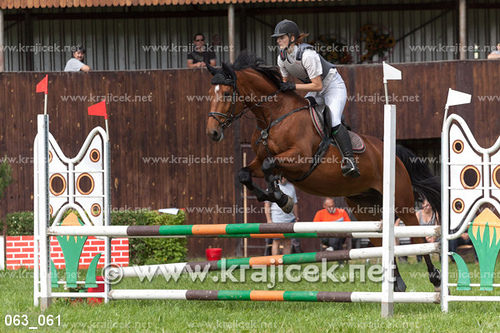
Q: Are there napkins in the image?
A: No, there are no napkins.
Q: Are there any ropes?
A: No, there are no ropes.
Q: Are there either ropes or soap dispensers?
A: No, there are no ropes or soap dispensers.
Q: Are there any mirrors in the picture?
A: No, there are no mirrors.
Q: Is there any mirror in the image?
A: No, there are no mirrors.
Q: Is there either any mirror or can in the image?
A: No, there are no mirrors or cans.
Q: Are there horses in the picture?
A: Yes, there is a horse.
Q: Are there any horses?
A: Yes, there is a horse.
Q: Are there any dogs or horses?
A: Yes, there is a horse.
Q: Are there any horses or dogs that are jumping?
A: Yes, the horse is jumping.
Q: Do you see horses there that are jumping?
A: Yes, there is a horse that is jumping.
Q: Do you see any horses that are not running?
A: Yes, there is a horse that is jumping .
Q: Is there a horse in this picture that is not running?
A: Yes, there is a horse that is jumping.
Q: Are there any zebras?
A: No, there are no zebras.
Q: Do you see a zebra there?
A: No, there are no zebras.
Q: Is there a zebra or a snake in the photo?
A: No, there are no zebras or snakes.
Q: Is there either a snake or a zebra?
A: No, there are no zebras or snakes.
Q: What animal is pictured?
A: The animal is a horse.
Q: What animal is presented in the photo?
A: The animal is a horse.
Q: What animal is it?
A: The animal is a horse.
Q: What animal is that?
A: This is a horse.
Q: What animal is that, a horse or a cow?
A: This is a horse.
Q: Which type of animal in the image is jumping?
A: The animal is a horse.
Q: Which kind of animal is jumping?
A: The animal is a horse.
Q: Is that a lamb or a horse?
A: That is a horse.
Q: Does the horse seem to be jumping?
A: Yes, the horse is jumping.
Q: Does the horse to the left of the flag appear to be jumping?
A: Yes, the horse is jumping.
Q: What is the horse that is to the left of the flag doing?
A: The horse is jumping.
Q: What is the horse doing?
A: The horse is jumping.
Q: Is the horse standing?
A: No, the horse is jumping.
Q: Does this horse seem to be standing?
A: No, the horse is jumping.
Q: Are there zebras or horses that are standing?
A: No, there is a horse but it is jumping.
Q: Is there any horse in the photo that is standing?
A: No, there is a horse but it is jumping.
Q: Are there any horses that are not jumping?
A: No, there is a horse but it is jumping.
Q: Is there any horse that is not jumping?
A: No, there is a horse but it is jumping.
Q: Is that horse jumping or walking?
A: The horse is jumping.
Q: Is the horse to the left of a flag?
A: Yes, the horse is to the left of a flag.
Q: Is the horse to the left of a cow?
A: No, the horse is to the left of a flag.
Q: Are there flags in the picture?
A: Yes, there is a flag.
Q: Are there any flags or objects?
A: Yes, there is a flag.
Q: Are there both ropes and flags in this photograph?
A: No, there is a flag but no ropes.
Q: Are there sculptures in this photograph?
A: No, there are no sculptures.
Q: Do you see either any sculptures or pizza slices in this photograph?
A: No, there are no sculptures or pizza slices.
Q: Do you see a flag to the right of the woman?
A: Yes, there is a flag to the right of the woman.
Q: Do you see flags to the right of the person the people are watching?
A: Yes, there is a flag to the right of the woman.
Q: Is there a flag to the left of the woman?
A: No, the flag is to the right of the woman.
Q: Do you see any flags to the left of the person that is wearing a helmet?
A: No, the flag is to the right of the woman.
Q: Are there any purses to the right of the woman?
A: No, there is a flag to the right of the woman.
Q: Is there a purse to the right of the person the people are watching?
A: No, there is a flag to the right of the woman.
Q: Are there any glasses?
A: No, there are no glasses.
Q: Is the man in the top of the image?
A: Yes, the man is in the top of the image.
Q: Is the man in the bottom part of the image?
A: No, the man is in the top of the image.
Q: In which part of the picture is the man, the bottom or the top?
A: The man is in the top of the image.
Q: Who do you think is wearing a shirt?
A: The man is wearing a shirt.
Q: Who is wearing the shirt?
A: The man is wearing a shirt.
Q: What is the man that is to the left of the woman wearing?
A: The man is wearing a shirt.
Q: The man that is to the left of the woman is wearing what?
A: The man is wearing a shirt.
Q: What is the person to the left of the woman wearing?
A: The man is wearing a shirt.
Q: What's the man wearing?
A: The man is wearing a shirt.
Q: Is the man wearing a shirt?
A: Yes, the man is wearing a shirt.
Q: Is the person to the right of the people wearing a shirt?
A: Yes, the man is wearing a shirt.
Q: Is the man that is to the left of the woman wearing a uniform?
A: No, the man is wearing a shirt.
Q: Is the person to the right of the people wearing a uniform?
A: No, the man is wearing a shirt.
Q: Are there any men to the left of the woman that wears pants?
A: Yes, there is a man to the left of the woman.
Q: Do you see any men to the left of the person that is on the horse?
A: Yes, there is a man to the left of the woman.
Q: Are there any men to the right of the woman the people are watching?
A: No, the man is to the left of the woman.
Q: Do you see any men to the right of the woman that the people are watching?
A: No, the man is to the left of the woman.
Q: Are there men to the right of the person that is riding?
A: No, the man is to the left of the woman.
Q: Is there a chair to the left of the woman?
A: No, there is a man to the left of the woman.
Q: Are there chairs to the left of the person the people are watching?
A: No, there is a man to the left of the woman.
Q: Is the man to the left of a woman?
A: Yes, the man is to the left of a woman.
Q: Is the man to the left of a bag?
A: No, the man is to the left of a woman.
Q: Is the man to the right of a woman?
A: No, the man is to the left of a woman.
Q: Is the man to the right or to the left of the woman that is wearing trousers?
A: The man is to the left of the woman.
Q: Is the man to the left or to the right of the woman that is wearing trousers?
A: The man is to the left of the woman.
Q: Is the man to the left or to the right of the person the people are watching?
A: The man is to the left of the woman.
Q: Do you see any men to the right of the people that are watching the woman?
A: Yes, there is a man to the right of the people.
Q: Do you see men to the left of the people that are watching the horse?
A: No, the man is to the right of the people.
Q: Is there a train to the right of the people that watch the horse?
A: No, there is a man to the right of the people.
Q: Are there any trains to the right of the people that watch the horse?
A: No, there is a man to the right of the people.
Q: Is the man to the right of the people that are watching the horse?
A: Yes, the man is to the right of the people.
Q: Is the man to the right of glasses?
A: No, the man is to the right of the people.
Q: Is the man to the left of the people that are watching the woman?
A: No, the man is to the right of the people.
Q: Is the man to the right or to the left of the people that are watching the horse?
A: The man is to the right of the people.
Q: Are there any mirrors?
A: No, there are no mirrors.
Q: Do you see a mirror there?
A: No, there are no mirrors.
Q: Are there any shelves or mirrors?
A: No, there are no mirrors or shelves.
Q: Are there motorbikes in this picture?
A: No, there are no motorbikes.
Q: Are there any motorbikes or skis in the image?
A: No, there are no motorbikes or skis.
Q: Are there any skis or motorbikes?
A: No, there are no motorbikes or skis.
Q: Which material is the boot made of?
A: The boot is made of leather.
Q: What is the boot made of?
A: The boot is made of leather.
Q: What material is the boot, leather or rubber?
A: The boot is made of leather.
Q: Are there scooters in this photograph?
A: No, there are no scooters.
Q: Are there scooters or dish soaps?
A: No, there are no scooters or dish soaps.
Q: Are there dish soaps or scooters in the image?
A: No, there are no scooters or dish soaps.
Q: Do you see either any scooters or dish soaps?
A: No, there are no scooters or dish soaps.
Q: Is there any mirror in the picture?
A: No, there are no mirrors.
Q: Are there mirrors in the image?
A: No, there are no mirrors.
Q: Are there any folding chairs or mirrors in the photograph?
A: No, there are no mirrors or folding chairs.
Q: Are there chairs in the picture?
A: No, there are no chairs.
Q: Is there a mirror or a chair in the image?
A: No, there are no chairs or mirrors.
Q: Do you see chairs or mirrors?
A: No, there are no chairs or mirrors.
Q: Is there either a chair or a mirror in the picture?
A: No, there are no chairs or mirrors.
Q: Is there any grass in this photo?
A: Yes, there is grass.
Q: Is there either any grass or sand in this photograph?
A: Yes, there is grass.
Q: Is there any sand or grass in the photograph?
A: Yes, there is grass.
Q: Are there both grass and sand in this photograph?
A: No, there is grass but no sand.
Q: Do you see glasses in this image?
A: No, there are no glasses.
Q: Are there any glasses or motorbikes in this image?
A: No, there are no glasses or motorbikes.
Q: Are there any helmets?
A: Yes, there is a helmet.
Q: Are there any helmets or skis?
A: Yes, there is a helmet.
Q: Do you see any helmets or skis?
A: Yes, there is a helmet.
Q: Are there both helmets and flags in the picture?
A: Yes, there are both a helmet and a flag.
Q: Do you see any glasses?
A: No, there are no glasses.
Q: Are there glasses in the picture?
A: No, there are no glasses.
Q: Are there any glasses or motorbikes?
A: No, there are no glasses or motorbikes.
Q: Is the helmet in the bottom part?
A: No, the helmet is in the top of the image.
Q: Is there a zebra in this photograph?
A: No, there are no zebras.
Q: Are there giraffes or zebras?
A: No, there are no zebras or giraffes.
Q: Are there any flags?
A: Yes, there is a flag.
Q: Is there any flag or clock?
A: Yes, there is a flag.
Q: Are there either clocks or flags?
A: Yes, there is a flag.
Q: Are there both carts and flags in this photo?
A: No, there is a flag but no carts.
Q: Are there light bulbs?
A: No, there are no light bulbs.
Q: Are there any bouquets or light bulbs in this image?
A: No, there are no light bulbs or bouquets.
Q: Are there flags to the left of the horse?
A: Yes, there is a flag to the left of the horse.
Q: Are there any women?
A: Yes, there is a woman.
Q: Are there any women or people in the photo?
A: Yes, there is a woman.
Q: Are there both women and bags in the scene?
A: No, there is a woman but no bags.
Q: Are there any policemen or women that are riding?
A: Yes, the woman is riding.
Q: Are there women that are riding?
A: Yes, there is a woman that is riding.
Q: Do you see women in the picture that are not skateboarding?
A: Yes, there is a woman that is riding .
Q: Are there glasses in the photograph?
A: No, there are no glasses.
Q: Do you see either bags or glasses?
A: No, there are no glasses or bags.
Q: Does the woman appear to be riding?
A: Yes, the woman is riding.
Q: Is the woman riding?
A: Yes, the woman is riding.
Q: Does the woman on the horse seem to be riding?
A: Yes, the woman is riding.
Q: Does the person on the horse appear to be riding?
A: Yes, the woman is riding.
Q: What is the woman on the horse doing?
A: The woman is riding.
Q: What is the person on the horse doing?
A: The woman is riding.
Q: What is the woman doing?
A: The woman is riding.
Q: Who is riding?
A: The woman is riding.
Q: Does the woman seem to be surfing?
A: No, the woman is riding.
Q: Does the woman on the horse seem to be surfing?
A: No, the woman is riding.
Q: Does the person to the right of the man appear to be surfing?
A: No, the woman is riding.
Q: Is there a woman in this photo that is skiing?
A: No, there is a woman but she is riding.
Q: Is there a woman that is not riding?
A: No, there is a woman but she is riding.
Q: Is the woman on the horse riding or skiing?
A: The woman is riding.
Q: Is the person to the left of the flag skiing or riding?
A: The woman is riding.